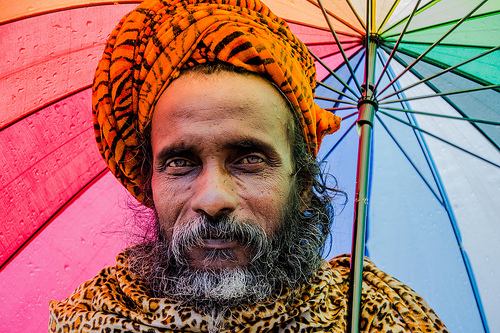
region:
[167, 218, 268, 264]
the gray and black mustache on a man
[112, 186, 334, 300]
a gray and black beard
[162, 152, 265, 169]
brown eyes of a man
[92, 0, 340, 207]
an orange and black turban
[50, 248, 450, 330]
a cheetah patterned scarf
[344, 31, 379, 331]
the metal pole of an umbrella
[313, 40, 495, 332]
multiple blue shades in an umbrella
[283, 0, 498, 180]
metal supporting wires of an umbrella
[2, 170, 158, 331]
the pink portion of an umbrella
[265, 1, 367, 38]
the inner orange section of an umbrella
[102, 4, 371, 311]
man with a grey and white beard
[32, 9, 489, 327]
man holding an umbrella above him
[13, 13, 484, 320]
man holding a rainbow umbrella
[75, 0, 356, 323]
man looking directly at camera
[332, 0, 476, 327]
silver handle and stokes of umbrella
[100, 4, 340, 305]
man with a tiger print turban wrapped around his head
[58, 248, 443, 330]
man with a leopard print scarf around neck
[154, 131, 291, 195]
wrinkle lines around mans eyes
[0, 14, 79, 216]
rain drops visible on umbrella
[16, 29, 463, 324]
man holding umbrella to keep him dry from rain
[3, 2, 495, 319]
The umbrella is different colors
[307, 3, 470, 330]
The umbrella pole is silver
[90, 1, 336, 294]
Man is wearing a hat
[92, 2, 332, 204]
The hat is striped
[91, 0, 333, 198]
The hat is orange and black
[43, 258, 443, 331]
Leopard print cloth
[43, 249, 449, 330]
The cloth is yellow, black, and orange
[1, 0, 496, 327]
The man is holding an umbrella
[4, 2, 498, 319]
The umbrella is pink, red, blue and green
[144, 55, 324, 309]
The man has a grey beard and mustache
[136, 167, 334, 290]
Man with a gray beard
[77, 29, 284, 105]
Man with orange towel on head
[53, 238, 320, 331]
man wearing a leopard print scarf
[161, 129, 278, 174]
man with gray eyes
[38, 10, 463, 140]
man holding umbrella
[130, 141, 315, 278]
Old man looking forward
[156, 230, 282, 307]
Man with a gray mustache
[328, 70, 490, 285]
Rainbow colored umbrella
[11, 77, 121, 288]
Red on the umbrella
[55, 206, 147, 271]
purple color on umbrella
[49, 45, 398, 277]
A man holding an umbrella.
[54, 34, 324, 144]
A man wearing a scarf on his head.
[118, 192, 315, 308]
A man with a grey beard.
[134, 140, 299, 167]
A man with light colored eyes.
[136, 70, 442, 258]
A man holding a rainbow colored unbrella.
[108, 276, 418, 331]
A man wearing a scarf around neck.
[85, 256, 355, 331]
A man wearing a leopard print scarf on neck.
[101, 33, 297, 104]
A man wearing tiger print scarf on head.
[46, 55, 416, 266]
A man underneath an umbrella.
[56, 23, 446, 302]
A rainbow umbrella over a man.